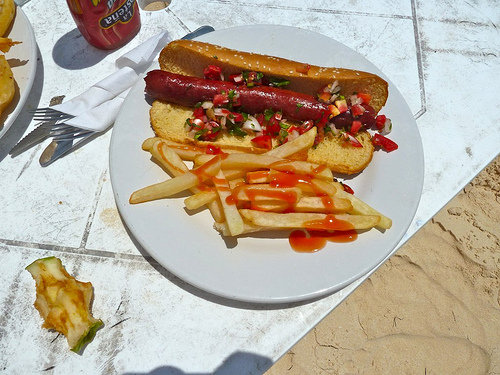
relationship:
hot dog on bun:
[136, 69, 391, 138] [137, 34, 399, 174]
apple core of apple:
[24, 256, 107, 355] [24, 256, 106, 350]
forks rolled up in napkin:
[3, 25, 218, 165] [39, 28, 182, 137]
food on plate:
[126, 125, 393, 255] [111, 22, 423, 311]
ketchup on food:
[194, 138, 360, 259] [126, 125, 393, 255]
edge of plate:
[153, 254, 340, 329] [111, 22, 423, 311]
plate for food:
[111, 22, 423, 311] [133, 31, 397, 254]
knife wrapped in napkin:
[5, 113, 86, 157] [39, 31, 195, 131]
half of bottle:
[61, 0, 151, 53] [64, 2, 141, 57]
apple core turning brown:
[24, 256, 107, 355] [36, 295, 80, 333]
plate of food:
[111, 22, 423, 311] [133, 31, 397, 254]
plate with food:
[111, 22, 423, 311] [126, 125, 393, 255]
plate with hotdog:
[111, 22, 423, 311] [136, 29, 397, 172]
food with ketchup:
[126, 125, 393, 255] [185, 137, 363, 254]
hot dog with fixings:
[142, 68, 378, 134] [184, 62, 394, 163]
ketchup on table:
[63, 0, 152, 60] [2, 0, 498, 371]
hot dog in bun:
[142, 68, 378, 134] [142, 37, 392, 177]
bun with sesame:
[142, 37, 392, 177] [186, 41, 362, 89]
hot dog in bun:
[142, 68, 378, 134] [137, 34, 399, 174]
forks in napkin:
[28, 25, 216, 125] [48, 28, 200, 136]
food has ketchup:
[126, 125, 393, 255] [173, 135, 368, 259]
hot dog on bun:
[142, 68, 378, 134] [137, 34, 399, 174]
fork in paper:
[29, 100, 91, 155] [50, 26, 186, 133]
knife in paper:
[5, 113, 86, 175] [50, 26, 186, 133]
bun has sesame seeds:
[131, 30, 391, 170] [184, 40, 258, 67]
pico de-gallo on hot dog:
[187, 65, 398, 155] [142, 68, 378, 134]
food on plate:
[133, 31, 397, 254] [111, 22, 423, 311]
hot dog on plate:
[142, 68, 378, 134] [111, 22, 423, 311]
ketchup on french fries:
[188, 152, 232, 193] [114, 129, 394, 243]